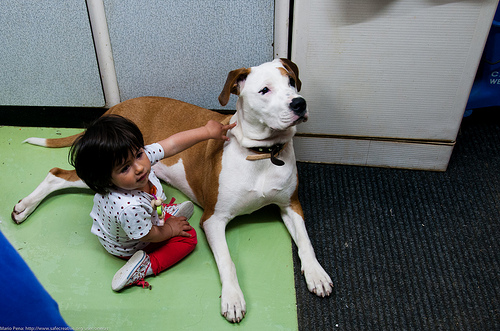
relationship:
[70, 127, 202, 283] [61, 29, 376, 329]
child petting dog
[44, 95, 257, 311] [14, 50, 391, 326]
toddler petting dog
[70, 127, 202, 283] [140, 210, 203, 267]
child wearing pants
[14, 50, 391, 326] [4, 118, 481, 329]
dog on floor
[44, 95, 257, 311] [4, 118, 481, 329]
toddler on floor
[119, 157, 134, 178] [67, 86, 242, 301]
eye on face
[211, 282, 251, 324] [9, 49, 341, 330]
paw in animal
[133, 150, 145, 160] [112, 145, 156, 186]
eye on a face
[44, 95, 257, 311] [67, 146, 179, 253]
toddler with shirt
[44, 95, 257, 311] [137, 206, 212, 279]
toddler with pants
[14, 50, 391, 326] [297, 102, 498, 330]
dog on floor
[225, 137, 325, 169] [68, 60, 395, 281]
collar on dog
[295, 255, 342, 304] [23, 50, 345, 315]
paw of animal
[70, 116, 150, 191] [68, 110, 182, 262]
head on body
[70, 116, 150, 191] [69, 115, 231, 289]
head on body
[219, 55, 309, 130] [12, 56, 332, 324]
head on body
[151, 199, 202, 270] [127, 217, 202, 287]
pants on girl's leg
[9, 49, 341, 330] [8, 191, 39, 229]
animal has paw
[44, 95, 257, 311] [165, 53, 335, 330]
toddler and dog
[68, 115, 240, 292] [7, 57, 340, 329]
little girl next to big dog